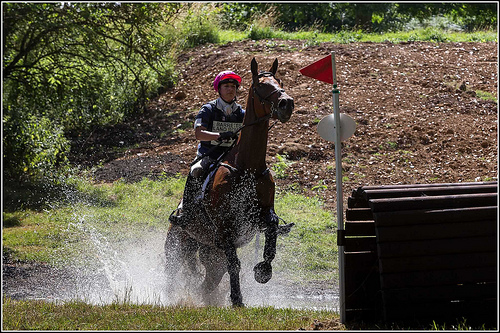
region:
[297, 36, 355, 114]
A red flag on a metal pole.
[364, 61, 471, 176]
Patch of dirt.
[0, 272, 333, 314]
Creek in a grassy area.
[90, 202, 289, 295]
Water spraying up on the bottom of a horse.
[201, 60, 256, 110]
Pink riding helmet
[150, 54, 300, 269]
Jockey on a brown horse's back.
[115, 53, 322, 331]
Brown horse running through water.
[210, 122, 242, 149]
Glove on person's hand.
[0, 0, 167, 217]
Tree with leaves.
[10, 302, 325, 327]
Grass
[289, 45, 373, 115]
Red flag on pole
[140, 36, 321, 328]
Horse galloping through water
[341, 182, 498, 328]
Wooden structure in field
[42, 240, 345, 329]
Body of water in woods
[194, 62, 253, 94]
Red helmet on rider's head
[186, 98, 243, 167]
Blue and white uniform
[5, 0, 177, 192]
Green trees in woods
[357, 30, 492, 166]
Dirt on side of hill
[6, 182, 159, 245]
Green grass in woods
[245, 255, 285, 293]
Black horse shoe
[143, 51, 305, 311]
person rising a horse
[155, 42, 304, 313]
person riding a horse through water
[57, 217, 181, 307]
water spray from horse running through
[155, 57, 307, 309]
large brown horse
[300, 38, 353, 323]
silver pole with a red flag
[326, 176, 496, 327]
circular wooden toy for horse to jump over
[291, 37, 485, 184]
brown hilly area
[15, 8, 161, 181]
green trees, bushes and grass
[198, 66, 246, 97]
person wearing pink riding helmet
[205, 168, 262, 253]
water spraying on horse as it runs through water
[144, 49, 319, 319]
A man riding his horse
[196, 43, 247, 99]
A red helmet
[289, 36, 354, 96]
A red flag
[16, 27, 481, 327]
A man riding his horse through water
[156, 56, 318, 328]
A brown horse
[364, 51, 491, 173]
Dirt on the ground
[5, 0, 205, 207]
Green trees and bushes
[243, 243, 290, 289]
The horse's hoof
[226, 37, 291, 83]
A pair of horse's ears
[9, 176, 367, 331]
Grass on the ground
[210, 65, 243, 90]
man wearing red helmet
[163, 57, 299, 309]
brown horse running through water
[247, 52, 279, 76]
horse's ears sticking up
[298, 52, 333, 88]
red flag on silver pole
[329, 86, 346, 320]
silver pole holding flag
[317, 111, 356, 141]
round sign on silver pole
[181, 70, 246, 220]
man riding brown horse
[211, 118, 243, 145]
white sign on front of shirt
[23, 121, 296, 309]
water splashing around horse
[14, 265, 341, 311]
water puddle near horse